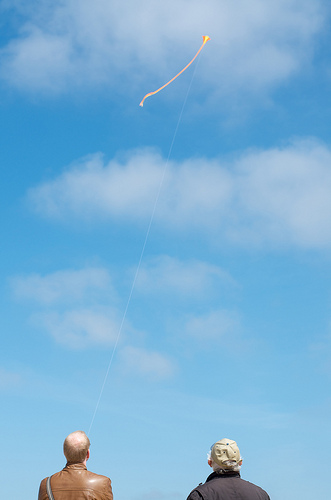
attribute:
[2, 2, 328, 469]
clouds — white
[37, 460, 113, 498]
jacket — brown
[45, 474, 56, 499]
strap — gray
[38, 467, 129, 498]
coat — brown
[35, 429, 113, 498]
gentleman — bald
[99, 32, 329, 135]
kite — yellow, orange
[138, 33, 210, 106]
kite — orange, yellow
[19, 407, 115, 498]
jacket — leather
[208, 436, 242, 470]
hat — cream colored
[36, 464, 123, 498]
jacket — brown, leather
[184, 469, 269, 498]
jacket — black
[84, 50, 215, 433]
string — long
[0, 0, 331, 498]
sky — blue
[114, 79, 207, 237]
string — white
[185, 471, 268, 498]
coat — black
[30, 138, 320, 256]
clouds — white, misty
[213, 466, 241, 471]
hair — white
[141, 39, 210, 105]
tail — long